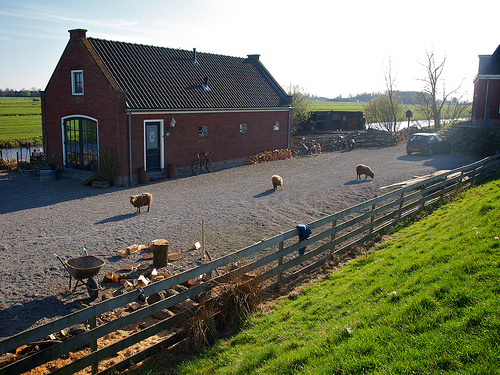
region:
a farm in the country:
[24, 19, 491, 343]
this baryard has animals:
[51, 138, 389, 325]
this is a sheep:
[114, 183, 179, 221]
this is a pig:
[341, 149, 399, 189]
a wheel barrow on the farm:
[45, 235, 102, 297]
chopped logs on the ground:
[111, 241, 184, 303]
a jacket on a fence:
[286, 209, 326, 267]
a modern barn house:
[33, 29, 298, 182]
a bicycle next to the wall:
[186, 142, 236, 183]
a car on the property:
[390, 129, 450, 161]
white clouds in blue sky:
[2, 10, 52, 43]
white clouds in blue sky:
[8, 40, 38, 74]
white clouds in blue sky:
[98, 10, 165, 40]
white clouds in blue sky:
[173, 1, 213, 30]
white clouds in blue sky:
[281, 27, 352, 78]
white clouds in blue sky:
[328, 10, 371, 60]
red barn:
[35, 21, 300, 173]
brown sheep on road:
[123, 185, 151, 210]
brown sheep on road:
[257, 155, 294, 205]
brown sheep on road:
[344, 155, 378, 183]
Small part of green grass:
[215, 339, 305, 367]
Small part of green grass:
[247, 298, 327, 365]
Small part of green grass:
[316, 318, 329, 372]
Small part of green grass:
[313, 269, 394, 366]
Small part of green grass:
[376, 226, 418, 274]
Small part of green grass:
[342, 294, 394, 374]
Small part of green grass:
[372, 272, 427, 373]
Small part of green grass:
[417, 240, 472, 307]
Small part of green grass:
[433, 295, 494, 374]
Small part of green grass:
[473, 184, 498, 289]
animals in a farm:
[10, 2, 490, 366]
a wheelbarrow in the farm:
[51, 235, 106, 306]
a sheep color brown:
[123, 186, 157, 214]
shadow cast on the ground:
[88, 205, 136, 232]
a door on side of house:
[137, 113, 169, 178]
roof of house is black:
[90, 33, 293, 121]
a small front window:
[59, 63, 89, 103]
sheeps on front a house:
[34, 20, 389, 217]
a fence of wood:
[13, 135, 497, 374]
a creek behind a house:
[0, 88, 471, 165]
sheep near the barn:
[126, 190, 153, 213]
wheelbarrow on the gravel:
[48, 244, 106, 301]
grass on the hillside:
[182, 180, 498, 371]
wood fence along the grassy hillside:
[1, 163, 497, 373]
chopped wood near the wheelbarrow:
[103, 235, 237, 326]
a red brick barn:
[36, 29, 295, 186]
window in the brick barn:
[68, 68, 85, 98]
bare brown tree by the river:
[406, 45, 466, 130]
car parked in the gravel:
[404, 128, 453, 158]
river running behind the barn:
[364, 115, 469, 132]